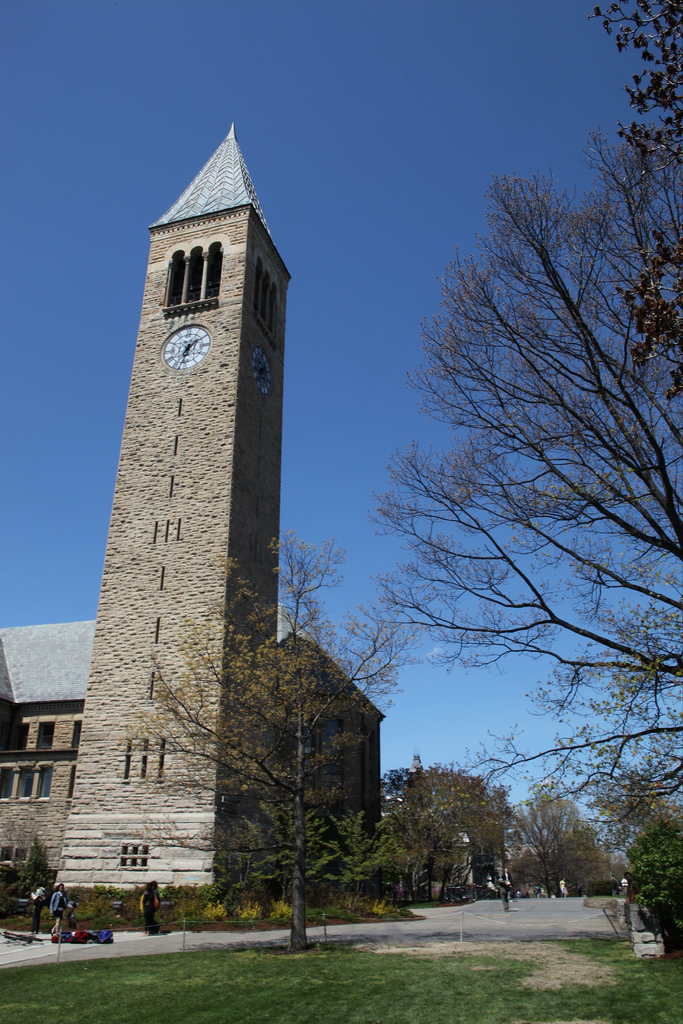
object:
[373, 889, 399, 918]
bushes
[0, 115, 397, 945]
building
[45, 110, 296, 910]
tower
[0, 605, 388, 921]
building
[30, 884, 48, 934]
person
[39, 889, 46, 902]
backpack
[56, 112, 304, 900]
clocktower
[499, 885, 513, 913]
pants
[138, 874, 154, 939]
person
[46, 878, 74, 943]
person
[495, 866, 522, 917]
person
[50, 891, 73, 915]
shirt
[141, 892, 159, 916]
shirt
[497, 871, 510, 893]
shirt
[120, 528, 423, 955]
tree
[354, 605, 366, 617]
leaves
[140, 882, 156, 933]
people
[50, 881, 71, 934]
people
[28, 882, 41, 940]
people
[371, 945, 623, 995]
grass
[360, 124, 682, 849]
tree branches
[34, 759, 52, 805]
windows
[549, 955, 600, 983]
dirt patch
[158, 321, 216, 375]
clock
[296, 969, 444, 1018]
lawn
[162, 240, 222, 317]
windows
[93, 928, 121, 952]
backpacks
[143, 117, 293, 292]
steeple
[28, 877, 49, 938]
person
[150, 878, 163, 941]
person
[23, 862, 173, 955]
group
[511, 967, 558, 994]
patch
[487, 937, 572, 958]
dirt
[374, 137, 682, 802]
tree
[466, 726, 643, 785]
branch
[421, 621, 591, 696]
branch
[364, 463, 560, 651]
branch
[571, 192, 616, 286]
branch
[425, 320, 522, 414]
branch